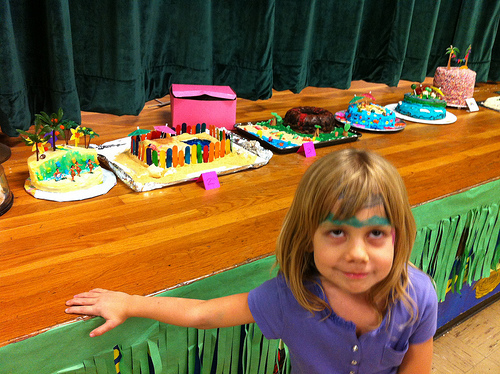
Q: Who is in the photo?
A: A girl.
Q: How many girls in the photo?
A: One.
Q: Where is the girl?
A: Near a table.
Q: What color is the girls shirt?
A: Purple.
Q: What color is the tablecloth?
A: Green.